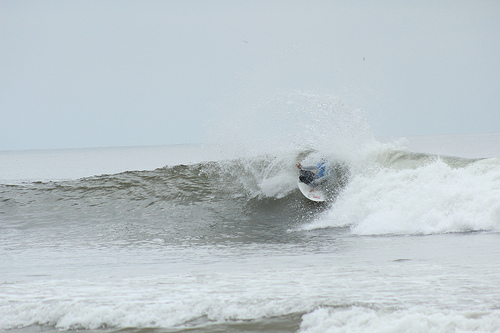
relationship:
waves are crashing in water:
[0, 150, 500, 236] [10, 137, 498, 331]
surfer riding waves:
[298, 153, 329, 190] [0, 150, 500, 236]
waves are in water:
[0, 150, 500, 236] [10, 137, 498, 331]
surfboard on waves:
[297, 179, 328, 202] [0, 150, 500, 236]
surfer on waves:
[298, 153, 329, 190] [0, 150, 500, 236]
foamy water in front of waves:
[6, 258, 497, 332] [0, 150, 500, 236]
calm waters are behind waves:
[7, 147, 222, 178] [0, 150, 500, 236]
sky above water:
[1, 1, 499, 118] [10, 137, 498, 331]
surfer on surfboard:
[298, 153, 329, 190] [297, 179, 328, 202]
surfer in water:
[298, 153, 329, 190] [10, 137, 498, 331]